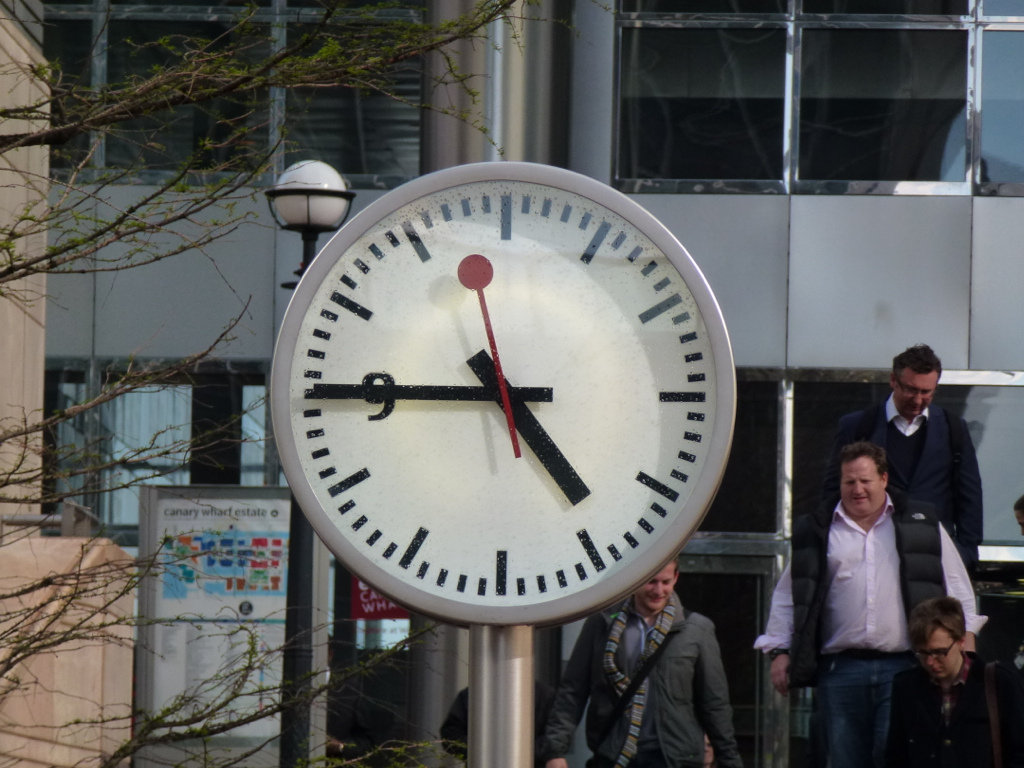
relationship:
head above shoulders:
[811, 433, 925, 536] [823, 398, 977, 446]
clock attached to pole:
[337, 156, 701, 624] [465, 621, 554, 749]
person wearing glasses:
[887, 594, 1021, 761] [910, 643, 955, 657]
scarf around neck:
[599, 602, 675, 672] [631, 591, 650, 620]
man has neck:
[548, 541, 754, 766] [631, 591, 650, 620]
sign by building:
[105, 468, 324, 738] [5, 3, 1012, 757]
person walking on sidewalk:
[868, 333, 963, 447] [765, 738, 827, 765]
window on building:
[715, 343, 834, 568] [5, 3, 1012, 757]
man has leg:
[754, 441, 989, 752] [816, 706, 867, 765]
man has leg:
[754, 441, 989, 752] [869, 711, 893, 762]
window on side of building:
[544, 0, 808, 212] [5, 3, 1012, 757]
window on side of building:
[281, 14, 428, 188] [5, 3, 1012, 757]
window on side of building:
[48, 8, 432, 186] [5, 3, 1012, 757]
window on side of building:
[543, 0, 1018, 188] [5, 3, 1012, 757]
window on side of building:
[528, 361, 1022, 763] [5, 3, 1012, 757]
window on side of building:
[38, 354, 473, 766] [5, 3, 1012, 757]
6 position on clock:
[491, 542, 508, 594] [268, 158, 736, 629]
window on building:
[801, 24, 964, 181] [5, 3, 1012, 757]